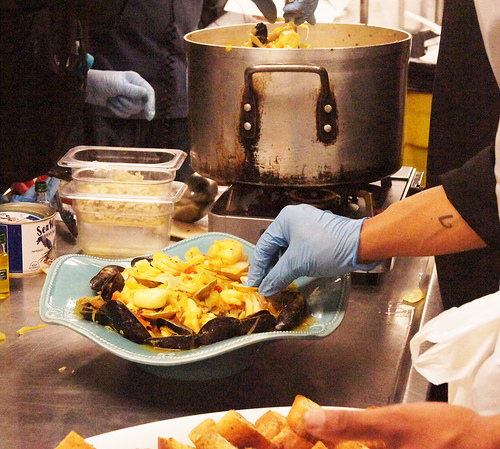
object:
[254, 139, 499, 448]
worker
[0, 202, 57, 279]
ingredients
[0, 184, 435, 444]
counter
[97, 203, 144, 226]
food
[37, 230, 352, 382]
bowl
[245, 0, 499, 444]
worker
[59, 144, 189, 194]
containers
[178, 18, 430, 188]
pot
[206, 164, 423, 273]
stove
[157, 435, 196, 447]
bread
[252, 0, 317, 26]
hand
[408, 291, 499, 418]
apron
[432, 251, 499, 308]
waist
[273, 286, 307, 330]
food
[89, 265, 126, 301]
food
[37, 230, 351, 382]
dish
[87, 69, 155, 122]
hand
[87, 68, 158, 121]
gloves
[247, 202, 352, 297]
hand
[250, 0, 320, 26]
gloves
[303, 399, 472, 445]
thumb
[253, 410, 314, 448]
bread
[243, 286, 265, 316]
chips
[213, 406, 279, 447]
bread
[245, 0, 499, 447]
man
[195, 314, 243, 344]
food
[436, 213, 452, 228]
tattoo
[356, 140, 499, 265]
arm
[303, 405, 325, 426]
fingernail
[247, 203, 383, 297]
glove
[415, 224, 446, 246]
vein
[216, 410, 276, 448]
potato wedge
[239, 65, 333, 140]
handle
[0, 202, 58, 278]
can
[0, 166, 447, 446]
table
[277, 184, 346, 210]
burner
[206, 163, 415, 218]
stove top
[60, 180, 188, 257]
container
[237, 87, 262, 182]
rust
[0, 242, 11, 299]
bottle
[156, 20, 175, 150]
wire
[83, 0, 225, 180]
person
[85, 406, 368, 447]
plate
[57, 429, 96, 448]
food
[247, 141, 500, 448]
person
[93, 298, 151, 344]
food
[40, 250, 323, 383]
platter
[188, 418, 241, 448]
bread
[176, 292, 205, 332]
chips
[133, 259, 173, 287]
chips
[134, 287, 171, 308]
chips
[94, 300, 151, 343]
mussel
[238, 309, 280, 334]
mussel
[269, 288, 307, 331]
mussel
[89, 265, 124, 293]
mussel